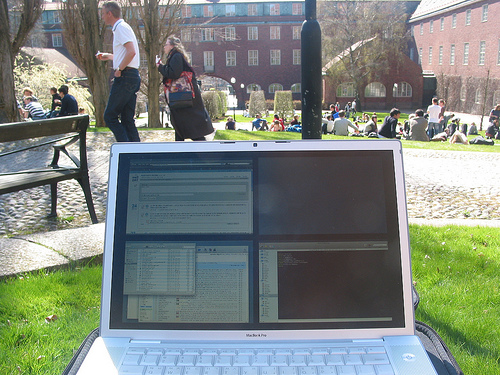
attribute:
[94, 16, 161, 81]
shirt — white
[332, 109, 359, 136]
person — pictured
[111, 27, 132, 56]
shirt — white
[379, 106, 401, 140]
person — pictured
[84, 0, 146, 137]
person — pictured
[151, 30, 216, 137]
person — pictured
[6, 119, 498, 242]
pathway — gray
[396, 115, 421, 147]
person — pictured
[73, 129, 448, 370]
laptop computer — on